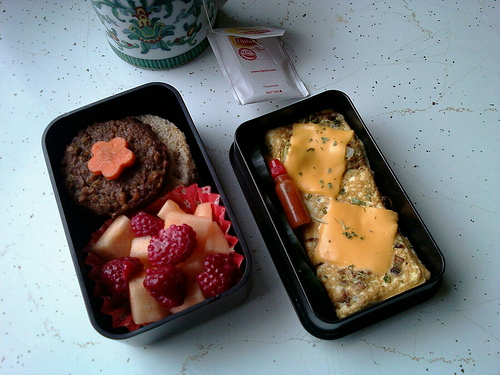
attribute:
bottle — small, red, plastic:
[269, 156, 310, 228]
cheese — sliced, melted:
[286, 122, 399, 274]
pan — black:
[230, 90, 448, 340]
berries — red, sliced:
[101, 216, 233, 300]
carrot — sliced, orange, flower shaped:
[86, 136, 135, 181]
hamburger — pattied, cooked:
[61, 119, 169, 216]